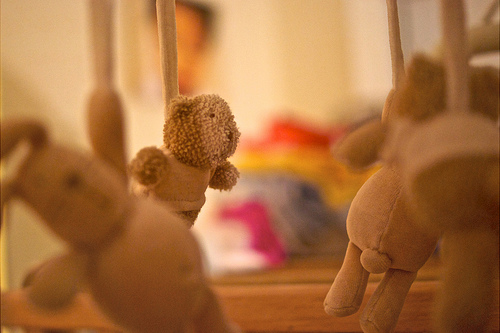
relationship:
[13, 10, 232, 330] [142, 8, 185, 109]
bears are attached to stick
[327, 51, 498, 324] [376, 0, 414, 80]
bears are attached to stick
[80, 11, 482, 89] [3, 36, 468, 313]
straps are attached to animals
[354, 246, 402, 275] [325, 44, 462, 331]
tail of animal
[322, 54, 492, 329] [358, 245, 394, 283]
animal has tail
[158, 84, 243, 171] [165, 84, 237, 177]
head has texture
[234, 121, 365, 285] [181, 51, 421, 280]
bed in distance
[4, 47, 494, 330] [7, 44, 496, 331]
animals floating in air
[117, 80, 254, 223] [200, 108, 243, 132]
animal has eyes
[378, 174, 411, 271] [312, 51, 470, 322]
seam seen on animal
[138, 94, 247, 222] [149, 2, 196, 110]
bear on pole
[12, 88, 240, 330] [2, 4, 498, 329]
bunny in photo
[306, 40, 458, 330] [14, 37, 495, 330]
bunny in photo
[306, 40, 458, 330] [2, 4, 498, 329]
bunny in photo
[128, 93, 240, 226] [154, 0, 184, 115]
teddy bear hanging on a rope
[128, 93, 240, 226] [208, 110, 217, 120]
teddy bear has eye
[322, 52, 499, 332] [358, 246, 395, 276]
teddy bear has tail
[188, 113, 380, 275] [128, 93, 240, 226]
object behind teddy bear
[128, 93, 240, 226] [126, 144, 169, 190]
teddy bear has arm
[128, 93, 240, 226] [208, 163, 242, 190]
teddy bear has arm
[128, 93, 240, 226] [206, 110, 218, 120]
teddy bear has eye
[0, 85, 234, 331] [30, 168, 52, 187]
teddy bear has eye